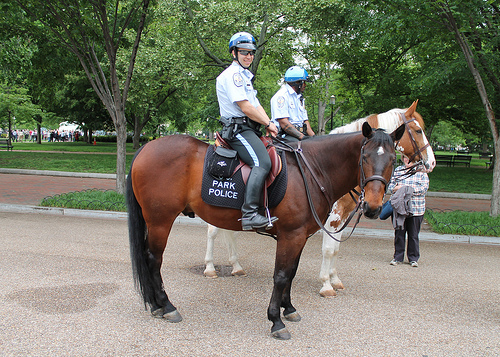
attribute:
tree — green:
[6, 2, 160, 194]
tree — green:
[124, 2, 296, 139]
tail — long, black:
[122, 173, 148, 305]